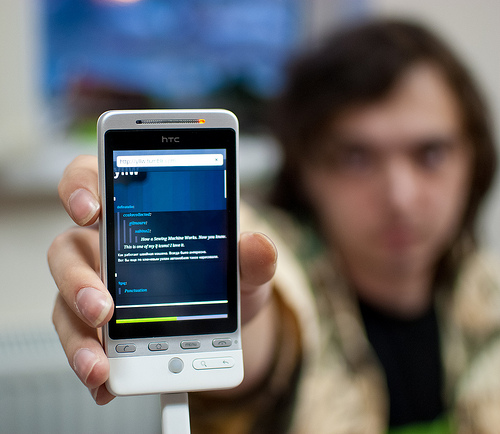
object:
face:
[305, 60, 476, 268]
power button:
[180, 340, 202, 350]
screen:
[106, 129, 238, 341]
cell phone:
[97, 107, 244, 397]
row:
[116, 300, 228, 309]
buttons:
[147, 341, 168, 351]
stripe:
[387, 409, 458, 433]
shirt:
[347, 279, 458, 434]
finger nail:
[73, 284, 113, 329]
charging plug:
[157, 392, 192, 434]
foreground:
[0, 189, 499, 434]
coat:
[171, 177, 498, 434]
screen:
[36, 0, 299, 116]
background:
[0, 0, 500, 209]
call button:
[115, 342, 136, 354]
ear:
[293, 144, 309, 190]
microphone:
[135, 118, 206, 125]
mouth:
[368, 218, 433, 245]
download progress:
[115, 314, 228, 325]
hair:
[270, 16, 495, 228]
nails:
[72, 348, 100, 385]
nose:
[377, 158, 419, 220]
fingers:
[45, 219, 115, 332]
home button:
[167, 356, 185, 374]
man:
[45, 17, 497, 433]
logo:
[160, 135, 180, 143]